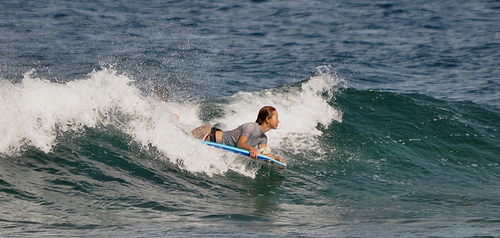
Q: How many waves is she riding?
A: One.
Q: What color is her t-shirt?
A: Grey.